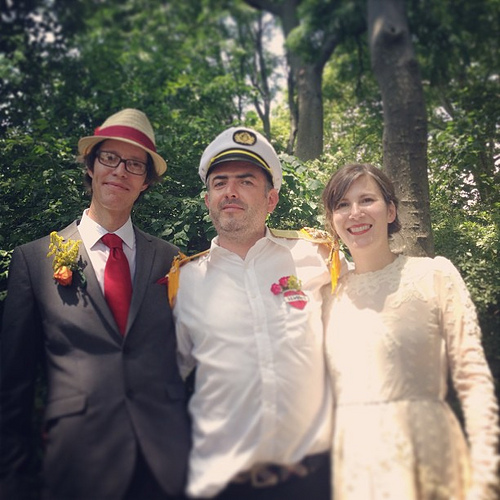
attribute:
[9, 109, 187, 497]
man in a suit coat — smiling, tall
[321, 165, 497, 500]
woman — smilng, bride, smiling bride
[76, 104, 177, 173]
hat — straw, straw with band, buff, red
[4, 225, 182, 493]
suit jacket — grey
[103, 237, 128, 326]
tie — red, deep red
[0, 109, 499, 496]
three people — standing, standing together, side by side, posing, smiling, happy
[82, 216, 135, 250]
collar — white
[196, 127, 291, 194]
captains hat — white cap, white, black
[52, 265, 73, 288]
red flower — rose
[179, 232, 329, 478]
white shirt — button-down style, partially untucked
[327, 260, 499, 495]
lace dress — beige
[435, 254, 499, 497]
sleeve — long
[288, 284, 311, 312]
heart — red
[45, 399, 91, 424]
flap — grey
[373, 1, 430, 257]
tree trunk — bark-covered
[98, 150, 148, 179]
glasses — black-rimmed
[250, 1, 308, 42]
tree branch — grey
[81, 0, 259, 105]
leaves — green, bunched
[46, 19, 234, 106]
leaves of tree — green